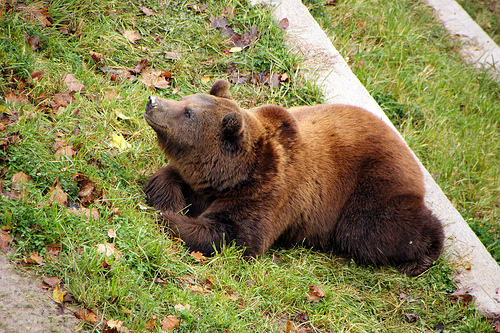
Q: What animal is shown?
A: Bear.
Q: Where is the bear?
A: On the grass.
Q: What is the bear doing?
A: Lying down.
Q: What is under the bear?
A: Grass.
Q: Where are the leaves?
A: On the ground.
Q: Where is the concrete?
A: Behind the bear.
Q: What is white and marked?
A: Areas.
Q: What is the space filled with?
A: Grass.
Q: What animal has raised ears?
A: The bear.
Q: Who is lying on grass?
A: The bear.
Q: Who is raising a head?
A: The bear.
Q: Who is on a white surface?
A: A bear.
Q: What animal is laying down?
A: A grizzly bear.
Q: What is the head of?
A: A grizzly bear.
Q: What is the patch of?
A: Grass.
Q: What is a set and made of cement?
A: Steps.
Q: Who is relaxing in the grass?
A: Brown bear.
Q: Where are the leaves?
A: In the grass.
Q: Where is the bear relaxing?
A: In the grass.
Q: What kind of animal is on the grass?
A: Bear.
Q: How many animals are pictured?
A: One.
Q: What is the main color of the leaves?
A: Brown.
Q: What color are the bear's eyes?
A: Black.